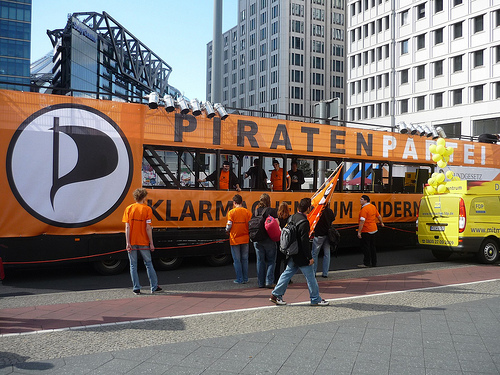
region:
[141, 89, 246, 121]
a group of six silver lights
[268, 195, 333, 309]
a man walking down the street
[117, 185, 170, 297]
a man with an orange t-shirt looking at a big bus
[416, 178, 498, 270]
a yellow vehicle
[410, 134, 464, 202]
group of yellow balloons attached to a vehicle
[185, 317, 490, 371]
stone paved walkway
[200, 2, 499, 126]
tall office buildings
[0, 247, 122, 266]
an orange dividing rope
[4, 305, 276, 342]
white line painted on the walkway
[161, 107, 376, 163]
the word piraten written in black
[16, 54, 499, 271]
a long orange and black sign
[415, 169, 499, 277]
a yellow van with balloons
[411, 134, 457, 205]
several yellow balloons on van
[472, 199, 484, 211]
blue letters on van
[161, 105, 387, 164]
black letters on yellow sign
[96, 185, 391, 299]
three guys in orange shirts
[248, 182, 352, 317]
a guy walking with a backpack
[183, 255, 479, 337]
shadow on ground from people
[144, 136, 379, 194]
people looking out an opening in sign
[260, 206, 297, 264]
a red bag being carried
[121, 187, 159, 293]
A man standing next to a train.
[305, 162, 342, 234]
A flag in someones hand.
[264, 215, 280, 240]
A pink bag on someones back.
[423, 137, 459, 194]
A group of balloons on top of a car.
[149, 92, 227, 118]
Some lights on top of a trailer.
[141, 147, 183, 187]
A stair case in the tailor.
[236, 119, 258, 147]
The letter R on the tailor.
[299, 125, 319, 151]
The letter T on the trailer.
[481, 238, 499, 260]
A tire on a yellow bus.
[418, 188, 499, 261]
A yellow van on some concrete.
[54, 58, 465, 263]
a bus on the road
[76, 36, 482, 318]
a bus on the street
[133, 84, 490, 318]
a large bus on the road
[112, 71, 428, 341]
a large bus ont he street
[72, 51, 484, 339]
an orange bus on the road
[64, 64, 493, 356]
a large bus on the street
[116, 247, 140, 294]
leg of a person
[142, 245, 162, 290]
leg of a person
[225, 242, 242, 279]
leg of a person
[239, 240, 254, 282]
leg of a person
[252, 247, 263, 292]
leg of a person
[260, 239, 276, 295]
leg of a person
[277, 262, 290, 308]
leg of a person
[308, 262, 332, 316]
leg of a person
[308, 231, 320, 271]
leg of a person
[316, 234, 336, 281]
leg of a person